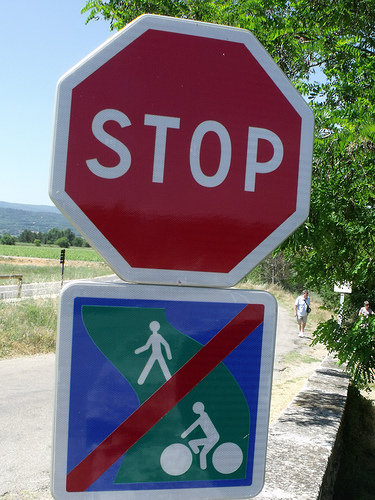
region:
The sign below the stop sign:
[47, 274, 277, 494]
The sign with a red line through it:
[48, 283, 284, 496]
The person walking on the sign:
[124, 316, 185, 385]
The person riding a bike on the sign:
[160, 400, 267, 484]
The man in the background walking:
[284, 281, 320, 335]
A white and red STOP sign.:
[48, 13, 315, 288]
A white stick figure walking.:
[135, 320, 172, 384]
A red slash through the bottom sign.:
[66, 303, 266, 491]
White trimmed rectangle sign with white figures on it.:
[49, 279, 275, 498]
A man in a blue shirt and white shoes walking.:
[293, 289, 311, 337]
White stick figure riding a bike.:
[161, 401, 244, 476]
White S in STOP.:
[85, 107, 132, 180]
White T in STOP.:
[143, 112, 180, 184]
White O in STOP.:
[190, 120, 231, 187]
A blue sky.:
[0, 1, 120, 208]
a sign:
[66, 31, 297, 273]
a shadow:
[298, 388, 343, 440]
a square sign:
[70, 289, 255, 487]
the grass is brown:
[3, 321, 28, 340]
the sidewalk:
[15, 391, 41, 434]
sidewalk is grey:
[2, 383, 38, 430]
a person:
[291, 290, 317, 346]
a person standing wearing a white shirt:
[294, 286, 313, 327]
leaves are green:
[315, 216, 347, 261]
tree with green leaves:
[331, 186, 364, 251]